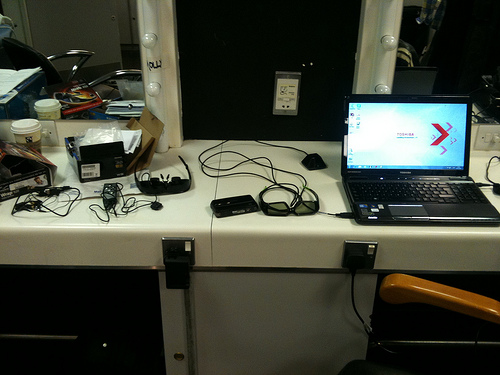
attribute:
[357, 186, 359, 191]
button — black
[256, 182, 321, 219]
sunglasses — black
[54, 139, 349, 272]
counter top — white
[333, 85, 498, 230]
laptop — black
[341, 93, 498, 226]
laptop — black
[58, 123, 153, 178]
box — open, black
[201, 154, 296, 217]
wires — black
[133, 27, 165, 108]
bulb — round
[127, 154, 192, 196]
sunglasses — black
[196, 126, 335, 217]
cord — black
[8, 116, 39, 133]
lid — white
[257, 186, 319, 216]
sunglasses — black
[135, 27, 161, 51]
bulb — white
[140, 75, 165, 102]
bulb — white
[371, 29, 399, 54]
bulb — white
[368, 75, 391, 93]
bulb — white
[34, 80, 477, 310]
table — open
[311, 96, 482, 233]
laptop — black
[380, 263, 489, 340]
armrest — wood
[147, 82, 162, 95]
bulb — round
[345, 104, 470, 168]
screen — on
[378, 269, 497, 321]
arm — wooden